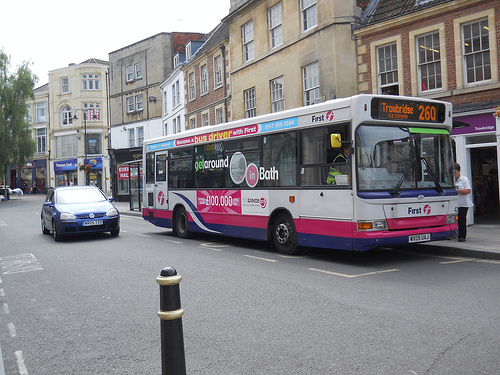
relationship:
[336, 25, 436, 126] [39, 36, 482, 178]
window on building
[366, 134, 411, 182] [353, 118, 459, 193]
glass on windshield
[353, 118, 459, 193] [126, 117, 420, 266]
windshield on bus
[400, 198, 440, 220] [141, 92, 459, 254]
logo ion front of bus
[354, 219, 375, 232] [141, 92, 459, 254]
light on bus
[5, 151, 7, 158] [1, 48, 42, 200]
leaf on tree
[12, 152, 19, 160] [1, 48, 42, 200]
leaf on tree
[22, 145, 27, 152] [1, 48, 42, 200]
leaf on tree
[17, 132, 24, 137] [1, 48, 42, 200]
leaf on tree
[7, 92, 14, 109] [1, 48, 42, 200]
leaf on tree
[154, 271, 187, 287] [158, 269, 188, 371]
rings are on pole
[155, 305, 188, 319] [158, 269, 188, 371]
rings are on pole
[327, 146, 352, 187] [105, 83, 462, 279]
driver in front of bus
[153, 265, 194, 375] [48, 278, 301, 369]
pole on street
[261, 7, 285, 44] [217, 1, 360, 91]
window are on building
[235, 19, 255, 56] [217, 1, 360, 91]
window are on building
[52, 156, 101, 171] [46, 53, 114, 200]
sign on building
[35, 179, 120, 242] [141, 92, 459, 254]
car next to bus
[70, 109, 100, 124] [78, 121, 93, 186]
street lights are on pole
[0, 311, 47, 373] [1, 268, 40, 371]
lines are on road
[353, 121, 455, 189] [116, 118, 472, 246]
windshield on bus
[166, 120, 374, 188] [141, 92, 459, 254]
windows are on bus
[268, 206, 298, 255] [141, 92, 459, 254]
tire on front of bus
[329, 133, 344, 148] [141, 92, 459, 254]
mirror on bus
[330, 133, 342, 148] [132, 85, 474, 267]
mirror on bus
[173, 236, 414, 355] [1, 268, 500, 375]
tarmac on road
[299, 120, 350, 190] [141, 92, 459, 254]
window on bus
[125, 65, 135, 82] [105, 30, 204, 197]
window on building